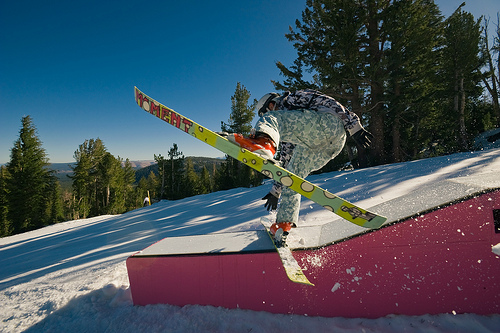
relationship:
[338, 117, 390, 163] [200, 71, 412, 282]
gloves on skier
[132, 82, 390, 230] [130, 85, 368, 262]
colorful skis on man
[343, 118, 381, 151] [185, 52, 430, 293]
gloves on man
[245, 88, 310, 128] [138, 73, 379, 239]
helmet on skier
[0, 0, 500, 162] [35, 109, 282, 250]
blue sky above trees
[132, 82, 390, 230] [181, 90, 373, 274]
colorful skis on skier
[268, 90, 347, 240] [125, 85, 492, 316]
man doing trick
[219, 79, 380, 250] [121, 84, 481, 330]
man performing tricks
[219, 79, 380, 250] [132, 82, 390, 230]
man wears colorful skis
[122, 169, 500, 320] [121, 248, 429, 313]
pink platform has a pink side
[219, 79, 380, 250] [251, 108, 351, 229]
man has on camoflage pants